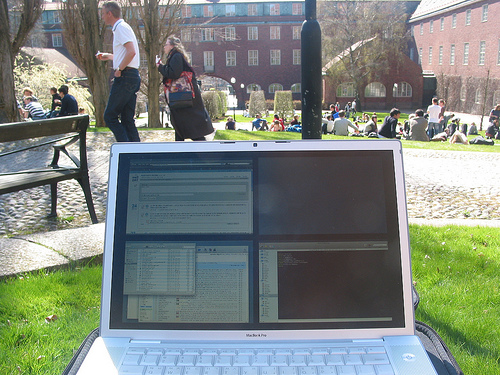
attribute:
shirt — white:
[94, 16, 161, 81]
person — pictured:
[332, 109, 359, 136]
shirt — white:
[111, 27, 132, 56]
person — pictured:
[379, 106, 401, 140]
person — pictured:
[84, 0, 146, 137]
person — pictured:
[151, 30, 216, 137]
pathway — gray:
[6, 119, 498, 242]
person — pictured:
[396, 115, 421, 147]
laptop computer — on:
[73, 129, 448, 370]